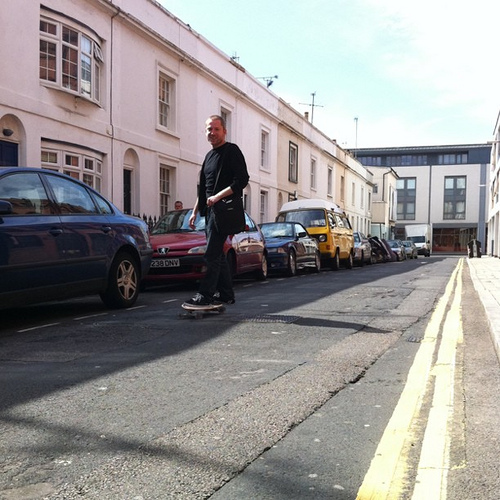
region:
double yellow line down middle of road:
[356, 248, 468, 498]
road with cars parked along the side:
[264, 214, 414, 439]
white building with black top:
[400, 143, 484, 258]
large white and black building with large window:
[428, 141, 487, 261]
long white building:
[23, 1, 389, 208]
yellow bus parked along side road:
[280, 194, 362, 274]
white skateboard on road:
[178, 299, 234, 325]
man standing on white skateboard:
[180, 111, 263, 334]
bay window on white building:
[22, 3, 120, 118]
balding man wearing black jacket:
[188, 111, 253, 240]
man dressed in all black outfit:
[178, 113, 251, 298]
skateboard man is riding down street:
[178, 297, 230, 319]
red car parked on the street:
[139, 198, 269, 278]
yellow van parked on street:
[281, 204, 360, 263]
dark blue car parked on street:
[3, 162, 158, 317]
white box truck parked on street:
[404, 223, 439, 256]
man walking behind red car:
[170, 196, 186, 227]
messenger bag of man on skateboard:
[206, 142, 245, 243]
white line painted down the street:
[359, 246, 484, 495]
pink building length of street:
[2, 3, 398, 223]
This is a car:
[4, 163, 153, 312]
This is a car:
[139, 194, 267, 307]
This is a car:
[251, 207, 325, 279]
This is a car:
[276, 191, 355, 274]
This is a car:
[346, 212, 371, 274]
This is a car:
[384, 226, 406, 263]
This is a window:
[35, 3, 111, 114]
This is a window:
[143, 49, 190, 160]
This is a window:
[208, 96, 243, 154]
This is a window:
[255, 116, 277, 176]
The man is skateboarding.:
[155, 101, 270, 339]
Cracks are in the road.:
[267, 295, 423, 427]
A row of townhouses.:
[0, 0, 402, 240]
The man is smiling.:
[190, 101, 237, 153]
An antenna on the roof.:
[290, 80, 332, 140]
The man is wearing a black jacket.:
[182, 136, 252, 231]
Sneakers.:
[170, 277, 236, 317]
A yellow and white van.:
[272, 190, 353, 265]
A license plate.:
[141, 240, 182, 275]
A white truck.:
[396, 215, 433, 261]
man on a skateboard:
[170, 105, 257, 319]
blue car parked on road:
[6, 157, 149, 317]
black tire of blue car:
[110, 250, 145, 307]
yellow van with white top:
[310, 192, 355, 269]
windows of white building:
[432, 165, 473, 227]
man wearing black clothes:
[200, 110, 246, 302]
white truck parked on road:
[404, 223, 434, 252]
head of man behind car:
[170, 197, 183, 212]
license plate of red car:
[152, 259, 177, 267]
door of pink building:
[2, 126, 24, 167]